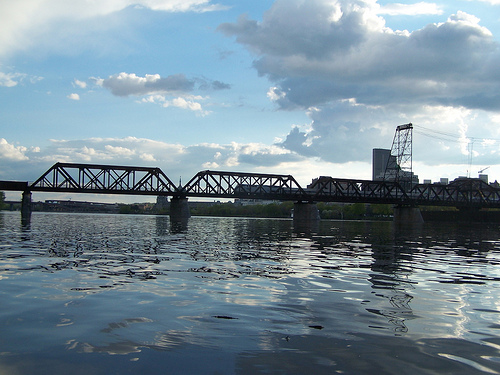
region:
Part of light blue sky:
[161, 34, 210, 57]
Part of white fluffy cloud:
[370, 28, 390, 45]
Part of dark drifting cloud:
[235, 24, 287, 47]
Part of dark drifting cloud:
[110, 76, 149, 90]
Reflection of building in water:
[363, 226, 408, 273]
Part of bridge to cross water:
[30, 159, 183, 196]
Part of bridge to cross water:
[183, 164, 304, 203]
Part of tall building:
[367, 144, 394, 174]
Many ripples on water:
[61, 222, 128, 245]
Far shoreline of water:
[80, 201, 135, 213]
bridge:
[28, 149, 303, 216]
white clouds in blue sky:
[72, 38, 162, 103]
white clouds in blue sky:
[21, 26, 51, 54]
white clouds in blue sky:
[64, 73, 126, 120]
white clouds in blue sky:
[215, 42, 287, 86]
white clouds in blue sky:
[222, 109, 264, 159]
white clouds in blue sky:
[312, 36, 394, 83]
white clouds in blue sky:
[417, 45, 479, 126]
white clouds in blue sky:
[242, 58, 293, 135]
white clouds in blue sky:
[115, 45, 182, 95]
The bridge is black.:
[1, 163, 499, 208]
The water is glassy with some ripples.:
[1, 212, 498, 372]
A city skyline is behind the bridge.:
[231, 146, 498, 203]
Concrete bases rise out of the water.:
[19, 196, 426, 226]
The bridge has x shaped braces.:
[26, 161, 499, 213]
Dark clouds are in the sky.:
[267, 47, 497, 106]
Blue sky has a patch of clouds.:
[1, 2, 303, 141]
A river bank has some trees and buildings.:
[17, 200, 462, 219]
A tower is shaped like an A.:
[383, 122, 415, 184]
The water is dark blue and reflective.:
[4, 211, 497, 373]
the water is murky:
[105, 225, 298, 336]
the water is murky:
[278, 265, 380, 345]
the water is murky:
[318, 305, 401, 372]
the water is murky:
[310, 276, 405, 356]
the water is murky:
[267, 293, 375, 328]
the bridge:
[90, 135, 307, 212]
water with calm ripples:
[6, 229, 497, 374]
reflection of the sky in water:
[6, 254, 322, 364]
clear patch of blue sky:
[147, 114, 249, 138]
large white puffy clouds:
[216, 0, 498, 116]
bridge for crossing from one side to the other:
[0, 161, 493, 210]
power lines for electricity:
[409, 119, 495, 147]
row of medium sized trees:
[191, 200, 288, 216]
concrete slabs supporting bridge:
[291, 201, 321, 218]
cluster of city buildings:
[418, 173, 493, 181]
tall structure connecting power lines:
[383, 123, 420, 185]